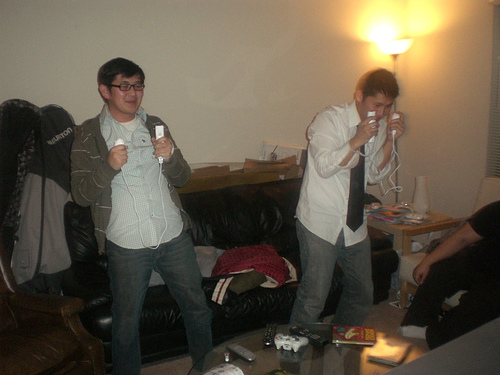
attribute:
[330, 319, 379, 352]
book — red 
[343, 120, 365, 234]
tie — black 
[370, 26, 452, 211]
lamp — black 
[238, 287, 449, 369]
table — glass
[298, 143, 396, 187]
elbows — bent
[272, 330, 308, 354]
game controller — white 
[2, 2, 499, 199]
walls — white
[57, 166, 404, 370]
sofa — black 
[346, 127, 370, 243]
tie — black 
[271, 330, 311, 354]
controller — xbox, wireless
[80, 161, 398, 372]
sofa — dark 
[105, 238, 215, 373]
jeans — Blue 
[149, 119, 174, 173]
game controller — white 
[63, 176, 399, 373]
couch — black 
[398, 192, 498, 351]
man — seated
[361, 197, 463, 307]
table — end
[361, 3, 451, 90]
lamp — bright, shining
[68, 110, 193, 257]
jacket — brown 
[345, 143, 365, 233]
tie — black 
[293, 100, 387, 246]
shirt — white 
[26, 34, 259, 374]
man — young 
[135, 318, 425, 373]
table — coffee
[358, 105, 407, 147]
hands — man's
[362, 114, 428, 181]
game — electronic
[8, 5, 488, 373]
room — cluttered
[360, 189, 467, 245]
surface — covered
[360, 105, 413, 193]
controls — remote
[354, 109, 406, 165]
controls — remote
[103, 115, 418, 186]
game — video